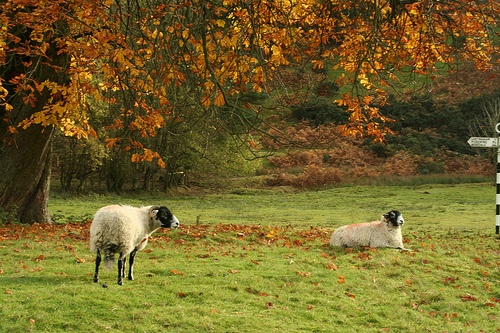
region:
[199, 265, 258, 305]
this is the grass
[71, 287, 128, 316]
the grass is green in color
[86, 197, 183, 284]
this is a sheep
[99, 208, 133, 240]
the wool is white in color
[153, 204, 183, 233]
the sheep's head is black in color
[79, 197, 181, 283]
the sheep is standing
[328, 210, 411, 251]
the sheep is seated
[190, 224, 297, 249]
these are dry leavers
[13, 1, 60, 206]
this is a tree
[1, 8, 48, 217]
the tree is tall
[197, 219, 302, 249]
Red and Yellow leaves on the grass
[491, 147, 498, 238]
Black and white patterned sign post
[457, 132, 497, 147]
Sign on post with an arrow pointing left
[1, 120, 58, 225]
Tree trunk on the grass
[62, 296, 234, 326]
Green grass in a field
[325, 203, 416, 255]
Sheep laying down in the grass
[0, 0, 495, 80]
Red and yellow leaves on a tree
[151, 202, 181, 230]
Black head of a sheep looking right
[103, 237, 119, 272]
White tail of a sheep pointing down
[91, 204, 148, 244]
White body of a sheep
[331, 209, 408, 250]
A white and black sheep lying on the ground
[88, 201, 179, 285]
A white and black fluffy ram looking to the right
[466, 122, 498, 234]
A black and white signpost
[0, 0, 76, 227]
A thick, twisting tree trunk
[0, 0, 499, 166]
Branches full of colorful autumn leaves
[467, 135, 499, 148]
A white arrow-shaped sign with tiny writing on it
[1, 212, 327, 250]
Many fallen leaves right under the branches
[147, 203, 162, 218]
The ram's horns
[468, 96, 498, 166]
A bare tree behind the signpost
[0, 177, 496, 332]
A light green, soft lawn with leaves scattered on it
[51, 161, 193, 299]
sheep standing in grass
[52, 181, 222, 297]
white sheep standing in grass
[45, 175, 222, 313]
attractive sheep standing in grass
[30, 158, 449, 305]
two sheep standing in grass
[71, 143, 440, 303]
couple sheep standing in grass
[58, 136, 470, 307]
some sheep out in grass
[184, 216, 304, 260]
leaves fallen on ground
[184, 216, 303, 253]
brown leaves on the ground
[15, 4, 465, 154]
autumn leaves on a tree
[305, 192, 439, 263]
sheep sitting on ground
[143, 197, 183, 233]
the head of a ram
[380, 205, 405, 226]
the head of a sheep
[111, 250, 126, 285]
the leg of a ram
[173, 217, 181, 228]
the nose of a ram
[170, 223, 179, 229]
the mouth of a ram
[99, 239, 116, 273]
the tail of the ram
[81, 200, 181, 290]
a ram on the grass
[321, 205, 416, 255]
a sheep on the ground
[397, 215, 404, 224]
the nose of a sheep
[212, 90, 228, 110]
an orange leaf